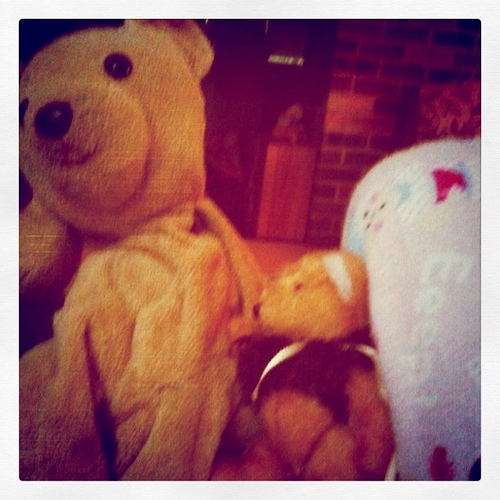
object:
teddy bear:
[20, 22, 261, 481]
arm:
[130, 237, 229, 392]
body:
[0, 203, 240, 481]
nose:
[34, 102, 74, 140]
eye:
[105, 52, 135, 80]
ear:
[132, 19, 215, 76]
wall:
[304, 20, 482, 247]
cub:
[227, 250, 395, 482]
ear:
[324, 250, 354, 303]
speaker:
[245, 135, 318, 240]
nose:
[251, 303, 264, 317]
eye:
[292, 283, 305, 291]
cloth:
[343, 138, 478, 481]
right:
[22, 22, 69, 243]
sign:
[264, 28, 310, 67]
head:
[253, 251, 369, 343]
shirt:
[248, 336, 383, 423]